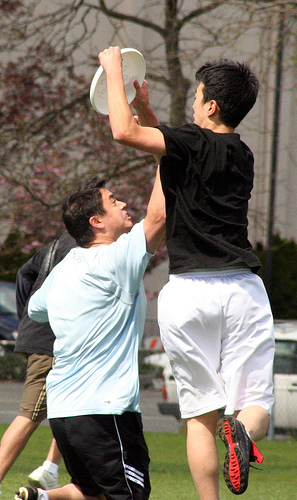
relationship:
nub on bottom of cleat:
[217, 417, 228, 426] [208, 408, 254, 493]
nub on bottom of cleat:
[222, 425, 229, 431] [210, 410, 260, 495]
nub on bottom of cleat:
[228, 448, 234, 454] [211, 409, 258, 492]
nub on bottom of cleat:
[228, 450, 234, 455] [205, 408, 262, 498]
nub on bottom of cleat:
[228, 458, 236, 464] [215, 408, 256, 492]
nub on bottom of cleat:
[221, 422, 230, 428] [215, 408, 256, 492]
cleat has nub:
[213, 410, 264, 498] [228, 452, 234, 458]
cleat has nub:
[213, 410, 264, 498] [226, 453, 235, 458]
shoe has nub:
[215, 410, 267, 497] [221, 422, 230, 428]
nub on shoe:
[228, 458, 236, 464] [214, 407, 262, 495]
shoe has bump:
[215, 410, 267, 497] [229, 467, 236, 472]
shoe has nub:
[215, 410, 267, 497] [228, 450, 234, 455]